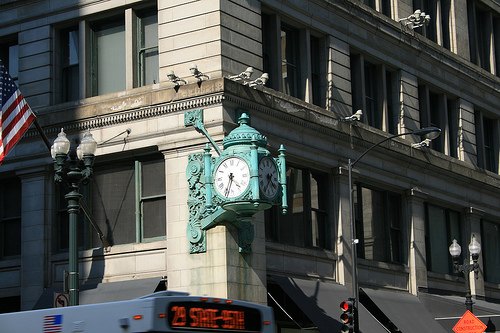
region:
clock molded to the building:
[148, 97, 295, 232]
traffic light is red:
[318, 292, 361, 327]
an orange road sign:
[436, 301, 490, 331]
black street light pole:
[319, 116, 459, 328]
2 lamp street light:
[432, 225, 487, 305]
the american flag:
[0, 57, 52, 162]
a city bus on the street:
[10, 299, 296, 331]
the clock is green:
[155, 100, 300, 230]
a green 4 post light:
[40, 108, 100, 281]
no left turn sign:
[36, 282, 75, 306]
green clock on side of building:
[210, 144, 290, 215]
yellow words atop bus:
[169, 300, 246, 330]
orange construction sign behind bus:
[449, 309, 488, 331]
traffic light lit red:
[337, 297, 355, 332]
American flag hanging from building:
[0, 59, 33, 164]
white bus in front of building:
[1, 289, 277, 331]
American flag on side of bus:
[41, 311, 65, 331]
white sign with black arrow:
[51, 290, 71, 307]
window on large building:
[55, 148, 167, 254]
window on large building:
[51, 0, 158, 104]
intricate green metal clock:
[157, 105, 292, 265]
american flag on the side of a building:
[0, 64, 41, 176]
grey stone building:
[0, 0, 499, 327]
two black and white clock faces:
[210, 153, 287, 205]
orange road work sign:
[450, 303, 485, 331]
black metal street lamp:
[338, 126, 443, 331]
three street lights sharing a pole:
[38, 126, 99, 316]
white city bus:
[0, 289, 277, 331]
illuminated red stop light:
[332, 291, 360, 331]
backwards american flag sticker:
[37, 313, 61, 331]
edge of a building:
[211, 24, 243, 84]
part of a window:
[131, 200, 158, 222]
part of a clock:
[241, 159, 260, 189]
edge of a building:
[428, 52, 440, 58]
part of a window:
[138, 182, 150, 201]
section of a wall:
[344, 239, 360, 305]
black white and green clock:
[211, 154, 250, 209]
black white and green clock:
[257, 154, 279, 208]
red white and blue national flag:
[11, 91, 36, 145]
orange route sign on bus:
[165, 294, 250, 326]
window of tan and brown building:
[49, 14, 151, 83]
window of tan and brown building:
[92, 155, 165, 239]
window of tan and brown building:
[257, 22, 329, 92]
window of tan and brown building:
[342, 177, 411, 258]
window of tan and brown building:
[423, 206, 460, 243]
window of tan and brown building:
[347, 53, 405, 142]